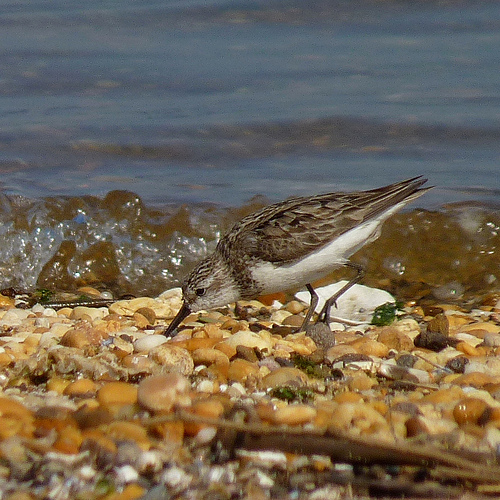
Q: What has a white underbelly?
A: The bird has a white underbelly.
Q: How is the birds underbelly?
A: The birds underbelly is white.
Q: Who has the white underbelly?
A: The bird has the white underbelly.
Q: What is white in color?
A: The birds underbelly.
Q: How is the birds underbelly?
A: The birds underbelly is white.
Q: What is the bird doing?
A: The bird is pecking on pebbles.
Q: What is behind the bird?
A: There is a wave of water behind the bird.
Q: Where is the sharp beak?
A: The bird is pointing it into the gravel bed.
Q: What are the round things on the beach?
A: Stones and pebbles.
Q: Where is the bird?
A: Amidst the stones, on the beach.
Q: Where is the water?
A: Beyond the stony beach.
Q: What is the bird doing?
A: Pecking at an item between the stones.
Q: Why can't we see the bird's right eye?
A: Because the bird is facing left.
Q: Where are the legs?
A: Below the bird's white underbelly.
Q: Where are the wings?
A: On either side of the bird.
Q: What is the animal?
A: Bird.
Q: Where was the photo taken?
A: Beach.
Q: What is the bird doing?
A: Eating.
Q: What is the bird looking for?
A: Food.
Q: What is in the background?
A: Water.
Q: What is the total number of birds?
A: 1.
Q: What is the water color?
A: Blue.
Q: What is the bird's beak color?
A: Brown.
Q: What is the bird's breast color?
A: White.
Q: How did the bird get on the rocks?
A: Flying.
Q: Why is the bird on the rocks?
A: Looking for something to eat.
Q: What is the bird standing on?
A: Small rocks.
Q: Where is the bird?
A: Sea shore.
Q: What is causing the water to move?
A: Wind.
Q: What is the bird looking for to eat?
A: Worms.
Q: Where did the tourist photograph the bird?
A: Beach.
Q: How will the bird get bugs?
A: Dig.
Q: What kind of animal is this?
A: Bird.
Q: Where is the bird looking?
A: The ground.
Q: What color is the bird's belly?
A: White.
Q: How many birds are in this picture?
A: One.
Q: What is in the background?
A: Water.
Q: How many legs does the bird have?
A: Two.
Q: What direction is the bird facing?
A: Left.